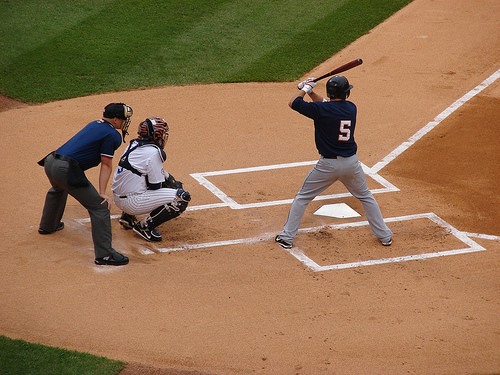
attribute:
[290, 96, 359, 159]
jersey — blue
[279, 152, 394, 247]
pants — light gray, gray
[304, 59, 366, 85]
baseball bat — brown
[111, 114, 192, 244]
catcher — squatting, crouched, for baseball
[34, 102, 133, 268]
umpire — for baseball, waiting for pitch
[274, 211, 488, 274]
batter's box — for left handers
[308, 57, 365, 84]
bat — for baseball, wood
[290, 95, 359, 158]
shirt — blue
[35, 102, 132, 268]
man — playing baseball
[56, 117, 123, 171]
shirt — blue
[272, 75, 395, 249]
batter — in hitting stance, waiting for pitch, batting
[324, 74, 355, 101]
helmet — dark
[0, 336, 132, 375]
grass — green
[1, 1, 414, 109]
grass — green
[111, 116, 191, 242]
baseball catcher — waiting for pitch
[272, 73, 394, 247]
man — playing baseball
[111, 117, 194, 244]
man — playing baseball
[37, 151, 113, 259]
pants — dark gray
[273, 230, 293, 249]
shoe — on foot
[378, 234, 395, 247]
shoe — on foot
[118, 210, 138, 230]
shoe — on foot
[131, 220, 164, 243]
shoe — on foot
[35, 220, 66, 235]
shoe — on foot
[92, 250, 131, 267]
shoe — on foot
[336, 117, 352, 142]
number — 5